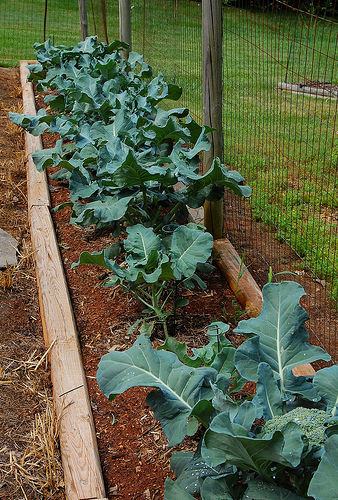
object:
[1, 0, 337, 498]
ground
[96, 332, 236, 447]
leaf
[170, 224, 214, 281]
leaf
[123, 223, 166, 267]
leaf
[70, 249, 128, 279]
leaf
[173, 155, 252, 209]
leaf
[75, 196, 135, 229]
leaf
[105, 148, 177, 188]
leaf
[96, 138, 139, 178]
leaf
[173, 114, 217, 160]
leaf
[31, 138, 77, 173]
leaf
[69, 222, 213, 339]
plant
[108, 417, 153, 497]
ground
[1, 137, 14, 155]
soil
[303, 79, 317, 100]
ground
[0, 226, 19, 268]
rock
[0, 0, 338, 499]
garden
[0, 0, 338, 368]
fence wire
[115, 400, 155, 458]
ground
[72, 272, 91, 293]
dirt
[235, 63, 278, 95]
floor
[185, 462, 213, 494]
drops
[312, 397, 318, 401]
drops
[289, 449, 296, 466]
drops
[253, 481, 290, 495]
drops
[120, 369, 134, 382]
drops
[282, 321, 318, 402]
moisture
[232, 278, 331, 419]
leaf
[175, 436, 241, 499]
leaf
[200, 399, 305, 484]
leaf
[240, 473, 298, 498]
leaf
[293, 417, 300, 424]
flower blossom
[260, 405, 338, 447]
bunch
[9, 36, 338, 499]
green flowers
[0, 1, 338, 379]
fence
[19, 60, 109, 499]
border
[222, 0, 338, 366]
wire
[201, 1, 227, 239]
board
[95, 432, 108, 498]
edge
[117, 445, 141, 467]
ground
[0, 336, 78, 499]
dry grass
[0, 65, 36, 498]
ground